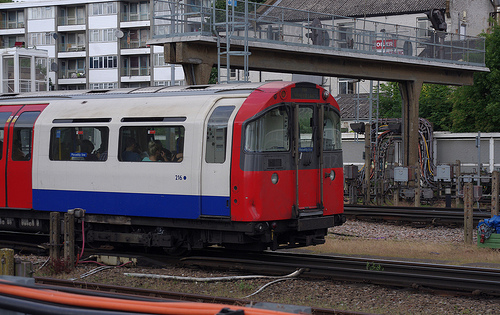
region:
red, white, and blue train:
[8, 83, 340, 248]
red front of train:
[222, 78, 346, 227]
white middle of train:
[34, 100, 234, 186]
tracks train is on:
[4, 211, 494, 299]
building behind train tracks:
[14, 4, 459, 131]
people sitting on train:
[45, 120, 181, 159]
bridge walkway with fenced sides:
[160, 1, 490, 73]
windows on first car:
[238, 95, 335, 165]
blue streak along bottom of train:
[28, 192, 226, 222]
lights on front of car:
[269, 167, 336, 189]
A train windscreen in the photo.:
[239, 101, 341, 150]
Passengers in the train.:
[117, 131, 183, 159]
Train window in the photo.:
[49, 124, 108, 159]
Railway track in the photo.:
[377, 260, 467, 283]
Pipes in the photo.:
[41, 292, 165, 312]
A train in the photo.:
[17, 82, 349, 232]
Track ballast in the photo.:
[316, 284, 426, 309]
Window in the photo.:
[85, 28, 119, 44]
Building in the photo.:
[59, 4, 152, 82]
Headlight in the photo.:
[266, 169, 286, 189]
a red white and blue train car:
[1, 81, 347, 253]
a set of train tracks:
[141, 240, 498, 297]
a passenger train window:
[117, 127, 184, 163]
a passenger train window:
[49, 125, 108, 163]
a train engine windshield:
[244, 103, 339, 154]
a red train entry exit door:
[0, 99, 47, 214]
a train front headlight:
[270, 173, 277, 186]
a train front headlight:
[328, 169, 338, 182]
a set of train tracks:
[345, 199, 495, 224]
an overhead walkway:
[146, 0, 488, 195]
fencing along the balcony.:
[311, 20, 392, 40]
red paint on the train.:
[259, 191, 279, 208]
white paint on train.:
[105, 170, 149, 180]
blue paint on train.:
[105, 198, 152, 205]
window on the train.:
[139, 136, 175, 152]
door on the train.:
[298, 148, 316, 205]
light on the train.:
[268, 173, 280, 183]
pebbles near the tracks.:
[334, 285, 372, 305]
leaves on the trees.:
[438, 92, 463, 106]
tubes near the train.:
[69, 293, 172, 313]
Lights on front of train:
[265, 166, 339, 190]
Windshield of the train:
[235, 98, 347, 174]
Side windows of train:
[44, 111, 191, 174]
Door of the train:
[0, 100, 52, 215]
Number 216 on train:
[168, 169, 186, 188]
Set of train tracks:
[138, 242, 498, 301]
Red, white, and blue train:
[0, 80, 361, 247]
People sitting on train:
[137, 136, 182, 163]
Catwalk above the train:
[140, 0, 486, 77]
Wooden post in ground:
[452, 176, 479, 250]